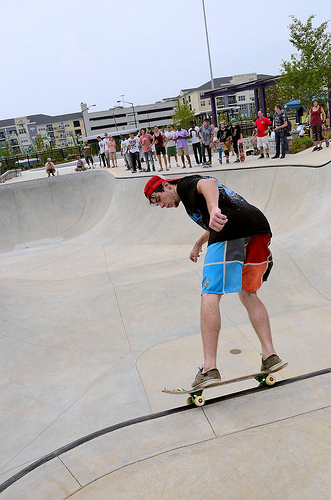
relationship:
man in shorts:
[67, 159, 316, 395] [181, 228, 317, 315]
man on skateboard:
[67, 159, 316, 395] [173, 366, 313, 402]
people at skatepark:
[106, 120, 326, 182] [2, 100, 304, 486]